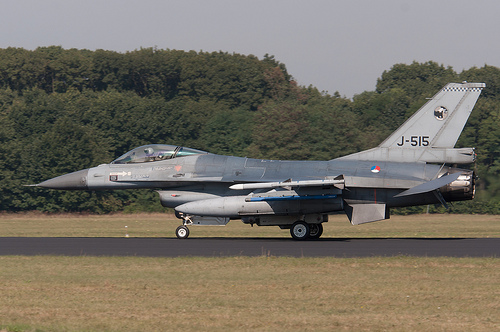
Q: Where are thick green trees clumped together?
A: Near the gray airplane.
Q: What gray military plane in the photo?
A: Gray plane on runway.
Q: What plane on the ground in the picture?
A: Military plane with black letters, reads, J-515.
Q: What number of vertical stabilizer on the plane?
A: Back of plane.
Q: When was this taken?
A: During the day.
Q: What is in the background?
A: A forest.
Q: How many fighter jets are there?
A: One.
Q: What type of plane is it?
A: An F-16.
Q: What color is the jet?
A: Grey.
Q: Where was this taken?
A: On an airbase.